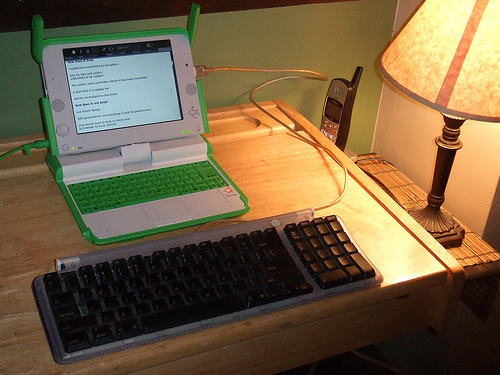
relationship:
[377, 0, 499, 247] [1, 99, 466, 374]
lamp on desk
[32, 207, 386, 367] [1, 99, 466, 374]
keyboard on desk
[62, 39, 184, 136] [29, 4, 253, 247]
screen on laptop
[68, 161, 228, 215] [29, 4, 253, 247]
keyboard on laptop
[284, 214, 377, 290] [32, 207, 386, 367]
number pad on keyboard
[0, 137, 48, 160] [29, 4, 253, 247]
wire attached to laptop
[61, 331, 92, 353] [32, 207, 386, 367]
key on keyboard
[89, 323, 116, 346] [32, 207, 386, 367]
key on keyboard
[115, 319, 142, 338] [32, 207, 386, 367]
key on keyboard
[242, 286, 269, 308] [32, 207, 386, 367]
key on keyboard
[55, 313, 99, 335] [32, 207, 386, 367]
key on keyboard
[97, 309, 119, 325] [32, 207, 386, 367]
key on keyboard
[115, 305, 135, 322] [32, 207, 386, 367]
key on keyboard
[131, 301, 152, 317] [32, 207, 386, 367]
key on keyboard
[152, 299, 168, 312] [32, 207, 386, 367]
key on keyboard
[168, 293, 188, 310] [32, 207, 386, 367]
key on keyboard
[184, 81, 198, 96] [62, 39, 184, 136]
speaker next to screen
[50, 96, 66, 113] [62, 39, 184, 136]
speaker next to screen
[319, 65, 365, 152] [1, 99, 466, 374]
telephone next to desk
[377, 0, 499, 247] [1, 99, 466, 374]
lamp next to desk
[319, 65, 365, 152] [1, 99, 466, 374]
telephone near desk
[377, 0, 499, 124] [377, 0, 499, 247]
lamp shade on lamp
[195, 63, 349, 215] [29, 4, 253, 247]
cord attached to laptop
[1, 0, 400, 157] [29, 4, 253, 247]
wall behind laptop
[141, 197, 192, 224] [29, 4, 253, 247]
touchpad on laptop